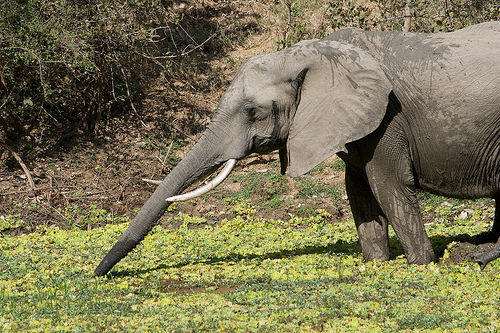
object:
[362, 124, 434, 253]
leg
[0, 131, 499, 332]
ground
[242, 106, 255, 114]
eye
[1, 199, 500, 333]
grass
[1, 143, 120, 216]
sticks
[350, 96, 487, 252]
wet body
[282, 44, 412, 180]
ear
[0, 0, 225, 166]
bush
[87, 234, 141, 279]
wet tip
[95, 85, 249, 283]
elephant trunk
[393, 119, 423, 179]
texture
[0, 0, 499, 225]
hill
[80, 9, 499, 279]
elephant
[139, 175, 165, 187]
tusk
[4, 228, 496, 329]
water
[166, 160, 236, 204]
tusk